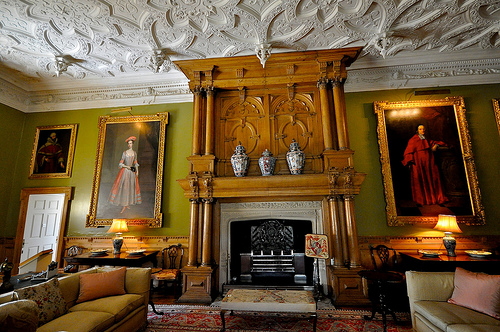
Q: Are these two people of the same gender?
A: No, they are both male and female.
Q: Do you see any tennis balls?
A: No, there are no tennis balls.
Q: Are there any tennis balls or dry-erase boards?
A: No, there are no tennis balls or dry-erase boards.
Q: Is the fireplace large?
A: Yes, the fireplace is large.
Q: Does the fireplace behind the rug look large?
A: Yes, the fireplace is large.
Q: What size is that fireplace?
A: The fireplace is large.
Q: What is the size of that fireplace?
A: The fireplace is large.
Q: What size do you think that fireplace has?
A: The fireplace has large size.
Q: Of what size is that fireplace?
A: The fireplace is large.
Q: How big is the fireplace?
A: The fireplace is large.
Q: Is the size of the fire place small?
A: No, the fire place is large.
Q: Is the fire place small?
A: No, the fire place is large.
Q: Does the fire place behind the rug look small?
A: No, the fireplace is large.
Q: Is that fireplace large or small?
A: The fireplace is large.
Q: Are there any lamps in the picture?
A: Yes, there is a lamp.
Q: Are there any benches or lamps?
A: Yes, there is a lamp.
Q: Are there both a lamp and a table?
A: Yes, there are both a lamp and a table.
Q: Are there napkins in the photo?
A: No, there are no napkins.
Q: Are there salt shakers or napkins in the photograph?
A: No, there are no napkins or salt shakers.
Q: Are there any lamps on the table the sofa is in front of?
A: Yes, there is a lamp on the table.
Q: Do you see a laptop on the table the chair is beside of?
A: No, there is a lamp on the table.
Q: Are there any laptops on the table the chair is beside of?
A: No, there is a lamp on the table.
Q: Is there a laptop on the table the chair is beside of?
A: No, there is a lamp on the table.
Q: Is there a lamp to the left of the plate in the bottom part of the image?
A: Yes, there is a lamp to the left of the plate.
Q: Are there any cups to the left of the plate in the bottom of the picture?
A: No, there is a lamp to the left of the plate.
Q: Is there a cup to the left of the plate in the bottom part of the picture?
A: No, there is a lamp to the left of the plate.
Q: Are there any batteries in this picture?
A: No, there are no batteries.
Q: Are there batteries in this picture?
A: No, there are no batteries.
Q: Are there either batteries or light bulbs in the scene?
A: No, there are no batteries or light bulbs.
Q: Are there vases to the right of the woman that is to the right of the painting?
A: Yes, there is a vase to the right of the woman.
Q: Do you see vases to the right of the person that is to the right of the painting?
A: Yes, there is a vase to the right of the woman.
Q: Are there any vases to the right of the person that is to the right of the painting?
A: Yes, there is a vase to the right of the woman.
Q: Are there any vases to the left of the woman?
A: No, the vase is to the right of the woman.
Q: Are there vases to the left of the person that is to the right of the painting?
A: No, the vase is to the right of the woman.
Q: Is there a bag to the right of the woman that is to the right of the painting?
A: No, there is a vase to the right of the woman.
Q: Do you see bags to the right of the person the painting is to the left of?
A: No, there is a vase to the right of the woman.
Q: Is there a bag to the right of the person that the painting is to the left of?
A: No, there is a vase to the right of the woman.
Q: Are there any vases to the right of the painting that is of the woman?
A: Yes, there is a vase to the right of the painting.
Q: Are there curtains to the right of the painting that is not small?
A: No, there is a vase to the right of the painting.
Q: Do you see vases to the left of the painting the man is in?
A: Yes, there is a vase to the left of the painting.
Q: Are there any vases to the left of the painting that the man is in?
A: Yes, there is a vase to the left of the painting.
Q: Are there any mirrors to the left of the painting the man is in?
A: No, there is a vase to the left of the painting.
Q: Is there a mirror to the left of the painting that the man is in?
A: No, there is a vase to the left of the painting.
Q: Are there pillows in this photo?
A: Yes, there is a pillow.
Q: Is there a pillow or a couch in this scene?
A: Yes, there is a pillow.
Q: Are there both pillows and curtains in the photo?
A: No, there is a pillow but no curtains.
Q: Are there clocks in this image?
A: No, there are no clocks.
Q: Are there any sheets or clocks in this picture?
A: No, there are no clocks or sheets.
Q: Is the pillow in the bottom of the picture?
A: Yes, the pillow is in the bottom of the image.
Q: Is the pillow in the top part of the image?
A: No, the pillow is in the bottom of the image.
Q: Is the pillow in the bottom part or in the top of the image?
A: The pillow is in the bottom of the image.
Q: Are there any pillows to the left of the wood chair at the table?
A: Yes, there is a pillow to the left of the chair.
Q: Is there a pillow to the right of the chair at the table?
A: No, the pillow is to the left of the chair.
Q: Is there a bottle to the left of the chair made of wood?
A: No, there is a pillow to the left of the chair.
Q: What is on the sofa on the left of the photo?
A: The pillow is on the sofa.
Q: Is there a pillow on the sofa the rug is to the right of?
A: Yes, there is a pillow on the sofa.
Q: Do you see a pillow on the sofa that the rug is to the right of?
A: Yes, there is a pillow on the sofa.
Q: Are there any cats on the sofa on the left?
A: No, there is a pillow on the sofa.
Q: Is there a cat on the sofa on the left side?
A: No, there is a pillow on the sofa.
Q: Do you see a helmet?
A: No, there are no helmets.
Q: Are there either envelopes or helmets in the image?
A: No, there are no helmets or envelopes.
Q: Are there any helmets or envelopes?
A: No, there are no helmets or envelopes.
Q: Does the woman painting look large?
A: Yes, the painting is large.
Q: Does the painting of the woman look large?
A: Yes, the painting is large.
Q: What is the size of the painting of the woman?
A: The painting is large.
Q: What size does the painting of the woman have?
A: The painting has large size.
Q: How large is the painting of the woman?
A: The painting is large.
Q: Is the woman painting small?
A: No, the painting is large.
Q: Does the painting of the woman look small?
A: No, the painting is large.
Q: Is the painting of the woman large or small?
A: The painting is large.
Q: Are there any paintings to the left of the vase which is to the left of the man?
A: Yes, there is a painting to the left of the vase.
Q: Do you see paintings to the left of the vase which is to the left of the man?
A: Yes, there is a painting to the left of the vase.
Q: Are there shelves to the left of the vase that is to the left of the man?
A: No, there is a painting to the left of the vase.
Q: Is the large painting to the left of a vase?
A: Yes, the painting is to the left of a vase.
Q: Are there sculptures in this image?
A: No, there are no sculptures.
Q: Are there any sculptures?
A: No, there are no sculptures.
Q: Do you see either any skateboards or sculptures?
A: No, there are no sculptures or skateboards.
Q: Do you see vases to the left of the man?
A: Yes, there is a vase to the left of the man.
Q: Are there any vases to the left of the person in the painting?
A: Yes, there is a vase to the left of the man.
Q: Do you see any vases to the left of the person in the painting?
A: Yes, there is a vase to the left of the man.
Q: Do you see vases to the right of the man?
A: No, the vase is to the left of the man.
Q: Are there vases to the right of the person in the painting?
A: No, the vase is to the left of the man.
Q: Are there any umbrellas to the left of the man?
A: No, there is a vase to the left of the man.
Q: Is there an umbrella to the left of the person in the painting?
A: No, there is a vase to the left of the man.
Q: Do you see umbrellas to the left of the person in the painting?
A: No, there is a vase to the left of the man.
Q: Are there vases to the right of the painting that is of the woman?
A: Yes, there is a vase to the right of the painting.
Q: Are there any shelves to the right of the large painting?
A: No, there is a vase to the right of the painting.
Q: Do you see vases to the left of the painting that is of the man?
A: Yes, there is a vase to the left of the painting.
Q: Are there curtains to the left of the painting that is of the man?
A: No, there is a vase to the left of the painting.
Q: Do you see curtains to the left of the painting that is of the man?
A: No, there is a vase to the left of the painting.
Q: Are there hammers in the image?
A: No, there are no hammers.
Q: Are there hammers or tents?
A: No, there are no hammers or tents.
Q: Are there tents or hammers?
A: No, there are no hammers or tents.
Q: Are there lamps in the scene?
A: Yes, there is a lamp.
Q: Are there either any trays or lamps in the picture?
A: Yes, there is a lamp.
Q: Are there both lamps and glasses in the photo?
A: No, there is a lamp but no glasses.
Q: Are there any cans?
A: No, there are no cans.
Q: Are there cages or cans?
A: No, there are no cans or cages.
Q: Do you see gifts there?
A: No, there are no gifts.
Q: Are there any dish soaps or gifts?
A: No, there are no gifts or dish soaps.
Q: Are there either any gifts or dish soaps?
A: No, there are no gifts or dish soaps.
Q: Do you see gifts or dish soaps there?
A: No, there are no gifts or dish soaps.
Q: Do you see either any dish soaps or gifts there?
A: No, there are no gifts or dish soaps.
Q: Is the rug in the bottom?
A: Yes, the rug is in the bottom of the image.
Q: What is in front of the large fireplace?
A: The rug is in front of the fireplace.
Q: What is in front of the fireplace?
A: The rug is in front of the fireplace.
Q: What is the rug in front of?
A: The rug is in front of the fireplace.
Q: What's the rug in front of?
A: The rug is in front of the fireplace.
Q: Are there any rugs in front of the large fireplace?
A: Yes, there is a rug in front of the fireplace.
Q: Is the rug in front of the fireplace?
A: Yes, the rug is in front of the fireplace.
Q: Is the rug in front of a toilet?
A: No, the rug is in front of the fireplace.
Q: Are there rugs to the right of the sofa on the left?
A: Yes, there is a rug to the right of the sofa.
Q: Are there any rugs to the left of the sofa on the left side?
A: No, the rug is to the right of the sofa.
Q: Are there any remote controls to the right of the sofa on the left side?
A: No, there is a rug to the right of the sofa.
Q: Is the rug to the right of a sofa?
A: Yes, the rug is to the right of a sofa.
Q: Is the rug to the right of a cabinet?
A: No, the rug is to the right of a sofa.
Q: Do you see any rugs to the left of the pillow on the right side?
A: Yes, there is a rug to the left of the pillow.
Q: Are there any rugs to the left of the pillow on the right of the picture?
A: Yes, there is a rug to the left of the pillow.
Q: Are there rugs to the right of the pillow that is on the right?
A: No, the rug is to the left of the pillow.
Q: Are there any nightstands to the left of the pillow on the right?
A: No, there is a rug to the left of the pillow.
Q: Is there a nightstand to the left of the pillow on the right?
A: No, there is a rug to the left of the pillow.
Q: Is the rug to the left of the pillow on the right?
A: Yes, the rug is to the left of the pillow.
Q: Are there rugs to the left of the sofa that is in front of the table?
A: Yes, there is a rug to the left of the sofa.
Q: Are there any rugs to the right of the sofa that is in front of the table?
A: No, the rug is to the left of the sofa.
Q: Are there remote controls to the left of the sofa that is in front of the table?
A: No, there is a rug to the left of the sofa.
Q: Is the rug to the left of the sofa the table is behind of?
A: Yes, the rug is to the left of the sofa.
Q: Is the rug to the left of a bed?
A: No, the rug is to the left of the sofa.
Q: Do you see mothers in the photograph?
A: No, there are no mothers.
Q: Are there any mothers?
A: No, there are no mothers.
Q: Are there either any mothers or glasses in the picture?
A: No, there are no mothers or glasses.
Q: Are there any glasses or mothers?
A: No, there are no mothers or glasses.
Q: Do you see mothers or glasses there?
A: No, there are no mothers or glasses.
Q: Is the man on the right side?
A: Yes, the man is on the right of the image.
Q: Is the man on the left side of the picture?
A: No, the man is on the right of the image.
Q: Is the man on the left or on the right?
A: The man is on the right of the image.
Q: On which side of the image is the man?
A: The man is on the right of the image.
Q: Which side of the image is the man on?
A: The man is on the right of the image.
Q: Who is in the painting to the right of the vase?
A: The man is in the painting.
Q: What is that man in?
A: The man is in the painting.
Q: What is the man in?
A: The man is in the painting.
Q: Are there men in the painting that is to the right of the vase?
A: Yes, there is a man in the painting.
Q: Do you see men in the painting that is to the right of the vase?
A: Yes, there is a man in the painting.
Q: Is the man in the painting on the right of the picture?
A: Yes, the man is in the painting.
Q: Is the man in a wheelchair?
A: No, the man is in the painting.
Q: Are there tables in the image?
A: Yes, there is a table.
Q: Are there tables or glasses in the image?
A: Yes, there is a table.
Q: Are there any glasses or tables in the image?
A: Yes, there is a table.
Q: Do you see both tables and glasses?
A: No, there is a table but no glasses.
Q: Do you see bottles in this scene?
A: No, there are no bottles.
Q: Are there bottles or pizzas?
A: No, there are no bottles or pizzas.